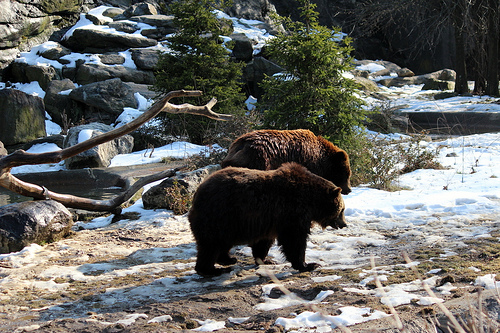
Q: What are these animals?
A: Bears.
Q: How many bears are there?
A: Two.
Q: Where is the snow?
A: On the ground.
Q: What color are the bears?
A: Brown.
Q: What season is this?
A: Winter.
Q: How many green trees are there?
A: Two.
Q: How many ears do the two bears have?
A: Four.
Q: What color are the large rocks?
A: Grey.